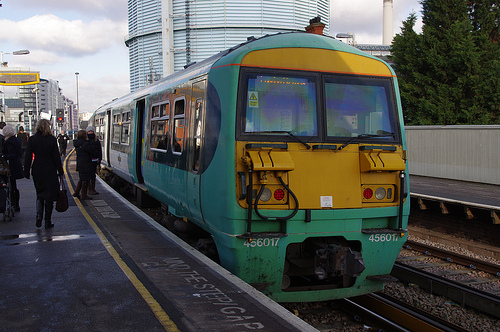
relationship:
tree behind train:
[388, 0, 499, 128] [79, 6, 417, 312]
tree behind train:
[387, 12, 436, 129] [79, 6, 417, 312]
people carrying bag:
[23, 119, 64, 230] [55, 172, 71, 211]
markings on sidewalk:
[105, 256, 152, 306] [1, 146, 299, 331]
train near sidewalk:
[79, 6, 417, 312] [1, 146, 299, 331]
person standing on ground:
[63, 112, 115, 212] [0, 146, 301, 331]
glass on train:
[245, 73, 400, 141] [79, 6, 417, 312]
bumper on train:
[239, 212, 398, 299] [94, 32, 414, 304]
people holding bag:
[23, 119, 64, 230] [55, 177, 69, 213]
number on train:
[365, 231, 396, 243] [79, 6, 417, 312]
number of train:
[365, 231, 396, 243] [79, 6, 417, 312]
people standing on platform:
[17, 66, 124, 207] [10, 209, 167, 324]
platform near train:
[10, 209, 167, 324] [38, 31, 428, 284]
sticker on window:
[243, 89, 258, 106] [243, 71, 313, 136]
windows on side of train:
[144, 99, 186, 154] [94, 32, 414, 304]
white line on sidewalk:
[133, 218, 322, 330] [3, 165, 200, 330]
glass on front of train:
[237, 60, 402, 147] [83, 24, 403, 295]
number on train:
[368, 233, 400, 242] [72, 59, 454, 302]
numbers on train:
[239, 227, 324, 253] [72, 59, 454, 302]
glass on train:
[245, 73, 400, 141] [65, 29, 420, 290]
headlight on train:
[256, 185, 272, 202] [79, 6, 417, 312]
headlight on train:
[373, 184, 388, 200] [79, 6, 417, 312]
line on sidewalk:
[56, 138, 181, 330] [2, 128, 322, 330]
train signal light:
[79, 6, 417, 312] [223, 135, 460, 233]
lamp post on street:
[73, 72, 80, 132] [2, 138, 188, 328]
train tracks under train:
[289, 222, 467, 328] [76, 50, 408, 312]